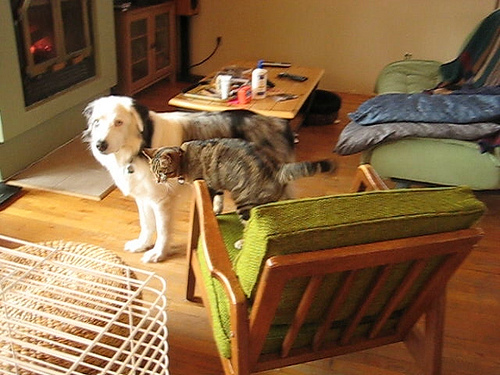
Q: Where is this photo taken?
A: In a house.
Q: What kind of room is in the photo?
A: A living room.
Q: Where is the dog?
A: Standing on the floor.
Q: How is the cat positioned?
A: Perched on a chair.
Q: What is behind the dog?
A: A fireplace.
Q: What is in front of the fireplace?
A: A mat.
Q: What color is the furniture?
A: Green.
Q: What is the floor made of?
A: Wood.